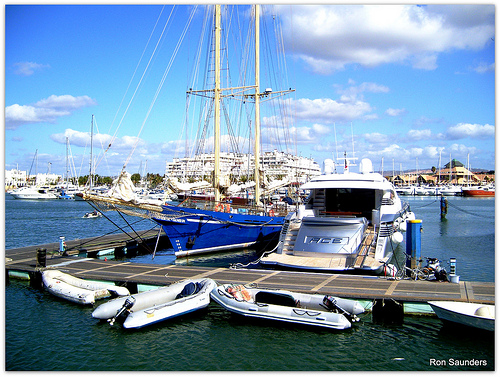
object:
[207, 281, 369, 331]
boat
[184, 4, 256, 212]
masts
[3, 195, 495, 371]
water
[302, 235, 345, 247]
word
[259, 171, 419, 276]
boat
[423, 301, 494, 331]
boat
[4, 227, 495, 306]
dock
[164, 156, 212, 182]
wall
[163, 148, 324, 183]
building